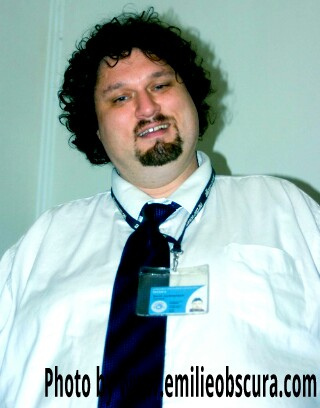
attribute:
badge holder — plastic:
[135, 264, 211, 315]